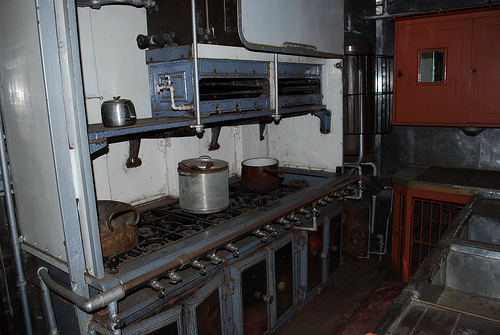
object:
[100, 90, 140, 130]
pot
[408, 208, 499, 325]
sink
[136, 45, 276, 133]
oven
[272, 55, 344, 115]
oven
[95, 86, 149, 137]
kettle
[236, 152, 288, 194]
kettle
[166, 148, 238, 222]
kettle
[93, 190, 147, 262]
kettle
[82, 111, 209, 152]
shelf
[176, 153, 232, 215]
pot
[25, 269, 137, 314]
pipe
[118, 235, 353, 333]
cabinets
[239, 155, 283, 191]
pot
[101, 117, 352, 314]
stove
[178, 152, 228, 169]
lid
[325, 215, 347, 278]
cabinets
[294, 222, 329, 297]
cabinets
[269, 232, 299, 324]
cabinets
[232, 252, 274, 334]
cabinets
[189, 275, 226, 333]
cabinets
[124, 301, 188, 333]
cabinets